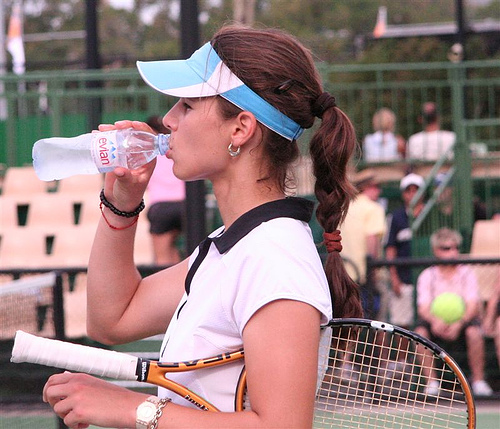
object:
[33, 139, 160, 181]
water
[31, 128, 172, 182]
bottle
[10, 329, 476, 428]
racket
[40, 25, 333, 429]
woman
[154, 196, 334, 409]
shirt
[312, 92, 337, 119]
hair band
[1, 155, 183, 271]
seats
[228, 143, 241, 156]
earring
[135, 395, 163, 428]
watch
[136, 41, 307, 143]
visor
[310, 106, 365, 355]
pony tail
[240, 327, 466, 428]
strings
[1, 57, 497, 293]
fence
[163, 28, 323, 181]
head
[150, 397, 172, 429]
bracelet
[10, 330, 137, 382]
handle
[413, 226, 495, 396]
woman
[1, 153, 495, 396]
stands